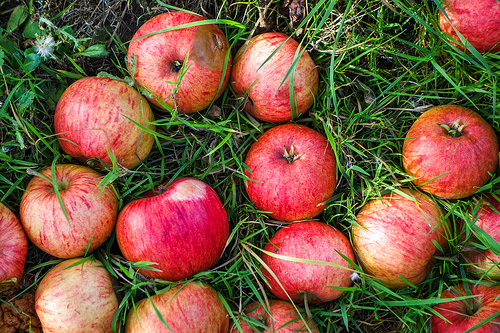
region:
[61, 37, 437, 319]
apples on the ground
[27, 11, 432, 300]
apples on the ground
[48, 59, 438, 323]
apples on the ground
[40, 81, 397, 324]
apples on the ground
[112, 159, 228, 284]
the apples are pink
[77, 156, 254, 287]
the apples are pink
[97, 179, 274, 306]
the apples are pink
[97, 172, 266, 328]
the apples are pink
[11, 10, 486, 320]
close-up of apples on grass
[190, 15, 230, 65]
bruise mark on the fruit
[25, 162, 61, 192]
stem of an apple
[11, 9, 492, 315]
sixteen apples on the ground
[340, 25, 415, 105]
patch of green grass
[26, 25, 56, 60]
white spore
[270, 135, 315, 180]
botton side of an apple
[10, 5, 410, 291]
group of similar sized fruit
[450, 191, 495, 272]
apple obscured by grass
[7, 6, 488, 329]
apples fallen on the earth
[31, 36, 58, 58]
A fluffy white dandelion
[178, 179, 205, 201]
A pale yellow patch on a red apple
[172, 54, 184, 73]
The stem of an apple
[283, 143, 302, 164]
The bottom of an apple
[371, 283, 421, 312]
Blades of green grass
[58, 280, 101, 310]
A pale yellow apple with patchy red lines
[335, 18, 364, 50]
Thin dry thatch underneath green grass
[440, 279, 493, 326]
The top of a red apply partially covered by green grass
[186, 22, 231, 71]
A rotten brown spot on the side of an apple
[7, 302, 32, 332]
A patch of dirt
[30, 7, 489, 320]
group of red apples in the green grass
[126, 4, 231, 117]
red apple laying in the grass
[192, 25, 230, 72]
large bruise on the side of an apple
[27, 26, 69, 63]
white dandelion in the grass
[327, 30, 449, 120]
patch of empty green grass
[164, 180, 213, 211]
light colored mark on the apple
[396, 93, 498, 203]
red apple laying with the bottom side up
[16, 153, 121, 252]
red apple sitting up stem side up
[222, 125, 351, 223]
red juicy apple laying in the grass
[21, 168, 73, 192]
green and brown apple stem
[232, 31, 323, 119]
apples on the ground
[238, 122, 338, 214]
apples on the ground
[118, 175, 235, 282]
apples on the ground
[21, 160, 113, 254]
apples on the ground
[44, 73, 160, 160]
apples on the ground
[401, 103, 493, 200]
apples on the ground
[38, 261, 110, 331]
apples on the ground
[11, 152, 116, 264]
apples in the grass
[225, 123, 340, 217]
apples in the grass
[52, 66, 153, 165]
apples in the grass